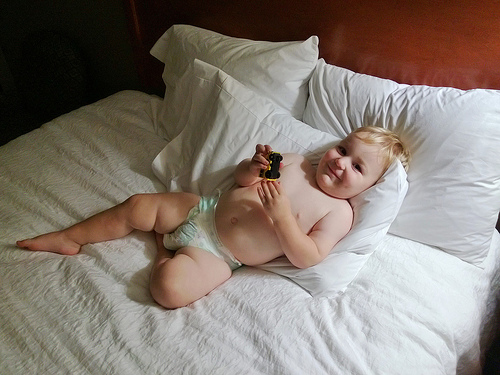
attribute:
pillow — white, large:
[160, 28, 498, 254]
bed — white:
[2, 88, 500, 374]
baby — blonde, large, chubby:
[63, 127, 414, 290]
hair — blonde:
[355, 126, 412, 161]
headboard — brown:
[130, 3, 500, 106]